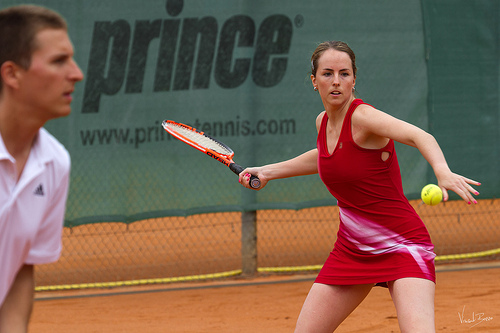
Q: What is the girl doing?
A: Hitting the ball.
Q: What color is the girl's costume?
A: Red.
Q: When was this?
A: Daytime.